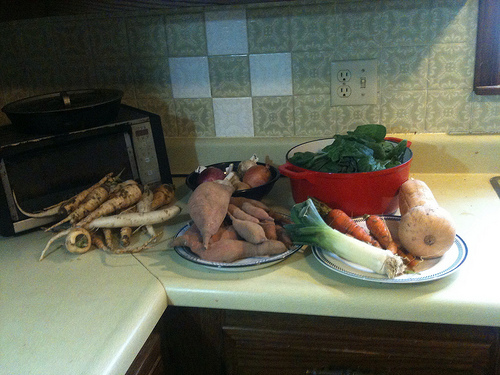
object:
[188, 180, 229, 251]
potatoes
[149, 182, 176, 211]
vegetables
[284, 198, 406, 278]
leek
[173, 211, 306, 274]
plate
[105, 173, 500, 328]
countertop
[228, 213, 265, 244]
sweet potato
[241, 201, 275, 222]
sweet potato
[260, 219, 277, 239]
sweet potato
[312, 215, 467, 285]
plate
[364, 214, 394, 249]
carrots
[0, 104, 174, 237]
microwave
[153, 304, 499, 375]
cabinets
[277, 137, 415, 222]
pot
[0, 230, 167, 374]
counter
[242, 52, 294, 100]
tile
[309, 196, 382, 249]
carrots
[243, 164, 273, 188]
onions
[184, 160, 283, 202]
bowl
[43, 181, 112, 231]
parsnips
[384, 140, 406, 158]
spinach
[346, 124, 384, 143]
spinach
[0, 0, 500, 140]
wall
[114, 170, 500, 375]
table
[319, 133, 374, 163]
greens